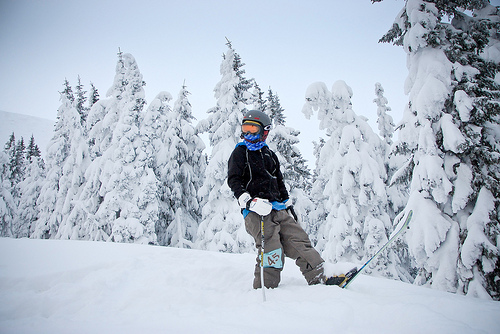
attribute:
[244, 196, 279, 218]
glove — white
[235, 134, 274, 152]
scarf — blue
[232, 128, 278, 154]
scarf — blue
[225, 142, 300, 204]
jacket — black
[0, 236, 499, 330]
snow — deep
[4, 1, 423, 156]
sky — blue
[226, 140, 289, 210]
jacket — black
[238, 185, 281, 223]
glove — white 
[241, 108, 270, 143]
helmet — grey